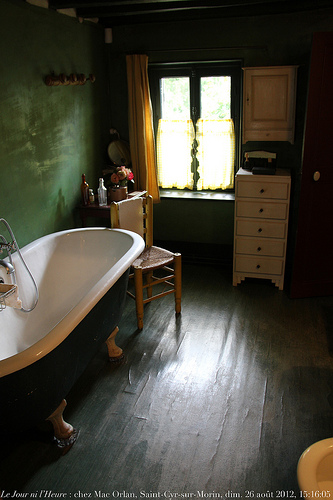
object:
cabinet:
[242, 65, 298, 144]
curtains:
[156, 118, 236, 191]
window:
[148, 61, 240, 191]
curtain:
[127, 55, 161, 204]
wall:
[0, 0, 113, 259]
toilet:
[296, 438, 332, 500]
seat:
[133, 247, 176, 269]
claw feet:
[46, 399, 78, 448]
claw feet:
[105, 326, 126, 366]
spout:
[0, 259, 16, 274]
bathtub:
[1, 227, 146, 449]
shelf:
[84, 142, 148, 238]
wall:
[203, 14, 253, 52]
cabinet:
[233, 174, 292, 290]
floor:
[0, 285, 332, 499]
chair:
[110, 194, 181, 330]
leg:
[174, 253, 182, 313]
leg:
[134, 269, 143, 329]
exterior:
[9, 44, 102, 213]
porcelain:
[0, 227, 145, 460]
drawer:
[237, 181, 288, 200]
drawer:
[237, 201, 287, 219]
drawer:
[237, 220, 286, 239]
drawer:
[235, 238, 284, 257]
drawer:
[235, 255, 283, 276]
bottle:
[97, 178, 107, 207]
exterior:
[0, 254, 137, 449]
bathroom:
[0, 0, 332, 498]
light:
[161, 75, 226, 116]